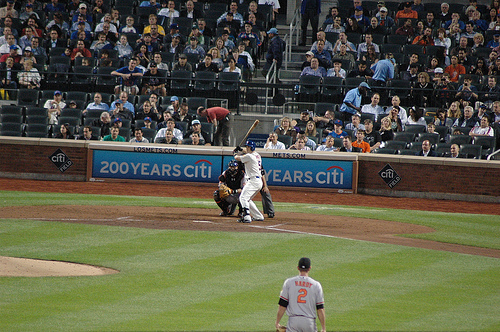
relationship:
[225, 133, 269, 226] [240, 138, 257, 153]
batter has head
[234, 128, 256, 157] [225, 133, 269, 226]
helmet on batter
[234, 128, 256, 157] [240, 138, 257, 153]
helmet on head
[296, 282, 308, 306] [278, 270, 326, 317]
number on shirt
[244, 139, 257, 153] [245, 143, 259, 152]
helmet on head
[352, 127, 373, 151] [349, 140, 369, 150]
man with shirt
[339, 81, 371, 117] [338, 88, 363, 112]
man with shirt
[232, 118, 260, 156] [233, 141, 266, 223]
bat held by batter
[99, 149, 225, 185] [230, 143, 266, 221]
sign behind a batter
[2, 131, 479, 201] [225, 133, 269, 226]
wall separating batter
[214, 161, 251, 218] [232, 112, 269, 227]
catcher kneeling behind batter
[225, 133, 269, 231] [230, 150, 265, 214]
batter in white uniform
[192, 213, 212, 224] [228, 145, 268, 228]
home plate by batter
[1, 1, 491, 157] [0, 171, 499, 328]
crowd watching ball field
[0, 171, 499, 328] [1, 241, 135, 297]
ball field has pitcher's mound